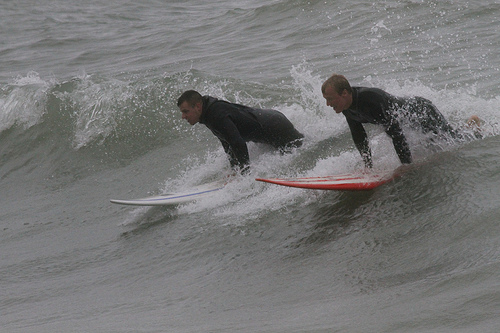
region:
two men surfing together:
[107, 73, 482, 208]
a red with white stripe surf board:
[253, 152, 433, 190]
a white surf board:
[107, 172, 251, 208]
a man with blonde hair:
[321, 72, 355, 116]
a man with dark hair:
[176, 88, 206, 125]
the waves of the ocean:
[0, 72, 171, 144]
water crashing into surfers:
[285, 15, 498, 140]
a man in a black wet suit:
[320, 74, 487, 175]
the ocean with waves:
[0, 0, 498, 330]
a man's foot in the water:
[464, 111, 486, 140]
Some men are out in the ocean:
[22, 7, 492, 303]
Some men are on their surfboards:
[41, 21, 496, 321]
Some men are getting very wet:
[30, 18, 495, 323]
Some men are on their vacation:
[42, 13, 497, 323]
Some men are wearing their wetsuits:
[50, 21, 491, 317]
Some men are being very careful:
[15, 20, 493, 310]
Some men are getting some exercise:
[36, 28, 492, 304]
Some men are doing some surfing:
[16, 33, 497, 306]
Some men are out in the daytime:
[37, 36, 492, 293]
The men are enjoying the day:
[38, 28, 455, 331]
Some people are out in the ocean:
[25, 8, 490, 321]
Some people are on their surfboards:
[21, 16, 492, 311]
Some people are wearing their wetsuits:
[45, 15, 485, 318]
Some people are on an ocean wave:
[21, 31, 463, 296]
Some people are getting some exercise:
[31, 21, 463, 326]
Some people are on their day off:
[63, 40, 494, 295]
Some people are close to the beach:
[46, 23, 483, 300]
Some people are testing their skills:
[48, 25, 496, 296]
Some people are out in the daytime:
[52, 26, 470, 291]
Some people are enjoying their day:
[52, 29, 482, 314]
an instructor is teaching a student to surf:
[11, 7, 493, 321]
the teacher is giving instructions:
[306, 73, 493, 132]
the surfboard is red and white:
[252, 151, 417, 202]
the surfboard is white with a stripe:
[96, 167, 246, 216]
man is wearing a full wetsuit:
[315, 75, 478, 197]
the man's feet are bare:
[316, 73, 492, 153]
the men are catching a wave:
[78, 59, 495, 234]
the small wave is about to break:
[9, 63, 499, 248]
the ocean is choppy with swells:
[8, 5, 496, 325]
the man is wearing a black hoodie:
[193, 88, 267, 176]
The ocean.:
[7, 3, 497, 331]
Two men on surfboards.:
[9, 6, 494, 319]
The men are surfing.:
[87, 71, 497, 227]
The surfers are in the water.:
[89, 54, 488, 259]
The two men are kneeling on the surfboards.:
[74, 70, 489, 230]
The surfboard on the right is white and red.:
[255, 161, 425, 196]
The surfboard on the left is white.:
[107, 156, 269, 218]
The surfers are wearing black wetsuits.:
[82, 52, 496, 233]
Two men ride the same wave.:
[89, 68, 492, 236]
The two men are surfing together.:
[100, 71, 489, 228]